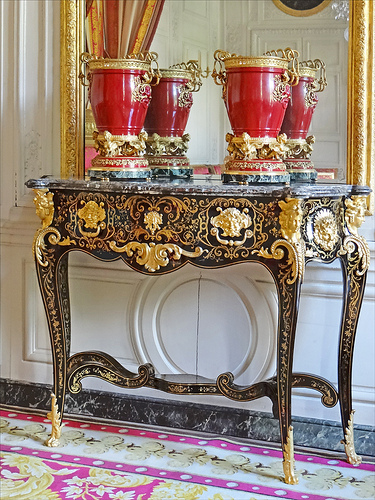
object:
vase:
[75, 41, 164, 186]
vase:
[209, 43, 303, 188]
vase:
[280, 48, 329, 181]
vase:
[140, 50, 211, 182]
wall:
[0, 0, 374, 457]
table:
[25, 165, 373, 487]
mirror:
[79, 0, 350, 182]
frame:
[57, 0, 90, 182]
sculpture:
[72, 197, 108, 239]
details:
[195, 197, 258, 253]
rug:
[0, 406, 374, 498]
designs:
[88, 468, 148, 490]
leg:
[272, 406, 301, 486]